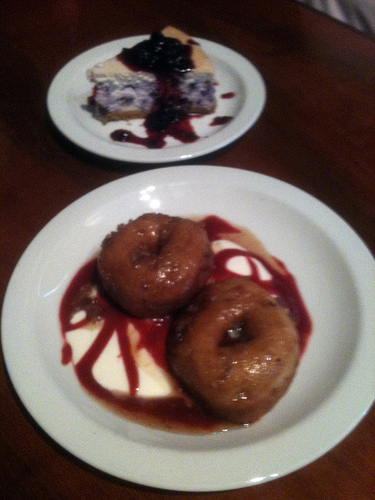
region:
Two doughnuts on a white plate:
[131, 200, 298, 388]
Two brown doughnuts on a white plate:
[93, 218, 311, 421]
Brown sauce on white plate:
[70, 272, 130, 383]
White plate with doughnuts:
[29, 187, 369, 491]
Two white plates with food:
[33, 28, 367, 499]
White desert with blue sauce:
[93, 16, 234, 147]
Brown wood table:
[280, 48, 351, 181]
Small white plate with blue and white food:
[34, 22, 277, 160]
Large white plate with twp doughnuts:
[17, 166, 373, 479]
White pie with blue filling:
[60, 26, 256, 169]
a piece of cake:
[45, 19, 264, 166]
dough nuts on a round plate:
[1, 165, 373, 495]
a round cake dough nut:
[171, 277, 298, 415]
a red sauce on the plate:
[64, 305, 139, 393]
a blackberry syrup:
[126, 120, 197, 145]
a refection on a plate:
[228, 470, 318, 486]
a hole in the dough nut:
[207, 315, 264, 362]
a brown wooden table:
[261, 21, 372, 161]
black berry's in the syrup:
[110, 122, 134, 146]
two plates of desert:
[0, 19, 372, 484]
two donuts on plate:
[23, 168, 374, 489]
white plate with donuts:
[0, 175, 366, 490]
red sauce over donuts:
[49, 200, 324, 442]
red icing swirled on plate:
[40, 202, 319, 437]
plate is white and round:
[16, 174, 369, 489]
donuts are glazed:
[94, 211, 304, 425]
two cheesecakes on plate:
[43, 19, 281, 164]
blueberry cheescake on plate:
[80, 73, 222, 119]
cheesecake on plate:
[87, 24, 226, 78]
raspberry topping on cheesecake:
[126, 37, 203, 142]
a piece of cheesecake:
[84, 26, 220, 118]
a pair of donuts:
[95, 208, 305, 428]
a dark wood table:
[16, 10, 374, 495]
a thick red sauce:
[67, 271, 196, 440]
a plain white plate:
[8, 166, 373, 491]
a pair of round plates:
[7, 21, 373, 488]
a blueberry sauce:
[125, 26, 189, 136]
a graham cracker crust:
[103, 103, 217, 118]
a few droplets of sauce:
[212, 85, 235, 123]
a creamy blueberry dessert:
[83, 25, 215, 113]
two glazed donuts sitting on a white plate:
[76, 206, 299, 408]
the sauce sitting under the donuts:
[69, 218, 310, 411]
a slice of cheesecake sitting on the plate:
[86, 23, 220, 129]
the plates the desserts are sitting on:
[25, 25, 368, 492]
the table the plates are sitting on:
[2, 4, 373, 488]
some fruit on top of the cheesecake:
[120, 33, 187, 78]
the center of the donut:
[214, 311, 255, 352]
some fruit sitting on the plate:
[106, 112, 192, 144]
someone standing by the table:
[313, 2, 374, 34]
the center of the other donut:
[141, 229, 168, 261]